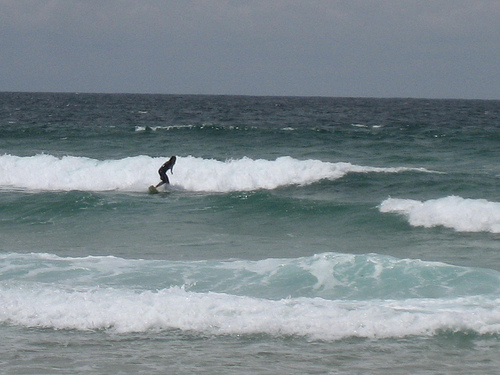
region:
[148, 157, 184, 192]
A person surfing a wave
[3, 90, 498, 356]
Blue water of the ocean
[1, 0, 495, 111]
A dreary and gray sky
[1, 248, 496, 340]
A wave crashing on the water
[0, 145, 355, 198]
A wave crashing on itself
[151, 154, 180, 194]
A person surfing in the ocean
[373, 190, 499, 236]
Waves crashing in the water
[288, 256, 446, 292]
Bubbly, blue water after a wave's crashed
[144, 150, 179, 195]
A surfer in a black wet suit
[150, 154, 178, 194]
A person on a surf board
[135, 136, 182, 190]
surfer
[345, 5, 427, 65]
white clouds in blue sky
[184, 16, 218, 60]
white clouds in blue sky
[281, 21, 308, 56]
white clouds in blue sky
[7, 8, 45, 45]
white clouds in blue sky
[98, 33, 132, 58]
white clouds in blue sky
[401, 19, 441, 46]
white clouds in blue sky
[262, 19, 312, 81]
white clouds in blue sky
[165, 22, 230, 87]
white clouds in blue sky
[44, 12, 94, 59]
white clouds in blue sky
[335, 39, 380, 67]
white clouds in blue sky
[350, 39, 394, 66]
white clouds in blue sky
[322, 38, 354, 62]
white clouds in blue sky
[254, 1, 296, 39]
white clouds in blue sky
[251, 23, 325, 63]
white clouds in blue sky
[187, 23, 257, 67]
white clouds in blue sky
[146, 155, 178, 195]
surfer rides surfboard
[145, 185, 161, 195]
surfboard is ridden by surfer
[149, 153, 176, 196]
surfer wears wetsuit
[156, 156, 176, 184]
wetsuit is worn by surfer in order to keep warm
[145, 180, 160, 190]
surfboard is pushed by wave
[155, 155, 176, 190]
sufer is pushed by wave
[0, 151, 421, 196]
wave has whitecap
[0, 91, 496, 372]
ocean is choppy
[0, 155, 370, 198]
wave is breaking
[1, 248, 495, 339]
wave is breaking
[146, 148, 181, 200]
There is a surfer.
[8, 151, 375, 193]
lots of waves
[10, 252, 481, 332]
The waves are white.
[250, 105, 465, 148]
The ocean is blue.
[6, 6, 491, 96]
The sky is hazy.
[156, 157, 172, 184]
The surfer is wearing a wetsuit.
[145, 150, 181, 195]
She is on a surfboard.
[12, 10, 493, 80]
The sky is blue.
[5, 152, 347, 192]
A wave is coming in.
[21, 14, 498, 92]
No birds in the sky.